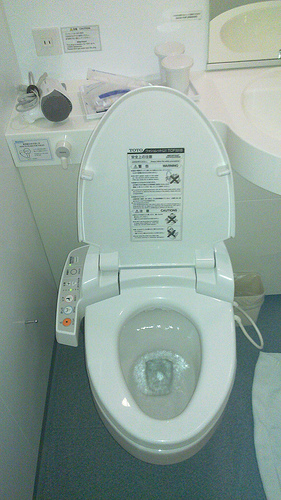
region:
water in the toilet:
[131, 353, 183, 387]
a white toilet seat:
[91, 284, 225, 439]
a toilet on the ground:
[81, 236, 239, 443]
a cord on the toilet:
[231, 304, 267, 347]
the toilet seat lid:
[82, 105, 219, 234]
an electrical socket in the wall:
[32, 27, 58, 51]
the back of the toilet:
[7, 67, 210, 123]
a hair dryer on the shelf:
[17, 72, 74, 115]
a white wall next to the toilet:
[8, 206, 32, 419]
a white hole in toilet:
[123, 311, 192, 459]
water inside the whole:
[130, 350, 180, 395]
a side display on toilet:
[46, 252, 87, 351]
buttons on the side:
[52, 251, 72, 339]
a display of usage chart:
[128, 138, 205, 253]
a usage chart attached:
[125, 149, 188, 248]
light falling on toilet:
[113, 388, 135, 411]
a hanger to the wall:
[19, 313, 41, 330]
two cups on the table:
[149, 25, 195, 88]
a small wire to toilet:
[234, 312, 279, 350]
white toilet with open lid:
[51, 86, 261, 472]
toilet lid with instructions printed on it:
[114, 133, 200, 254]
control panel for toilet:
[56, 239, 88, 351]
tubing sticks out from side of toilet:
[231, 294, 271, 358]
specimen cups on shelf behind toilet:
[153, 39, 195, 92]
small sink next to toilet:
[227, 77, 278, 167]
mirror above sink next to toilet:
[201, 4, 275, 77]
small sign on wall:
[59, 23, 109, 54]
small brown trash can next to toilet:
[233, 268, 268, 327]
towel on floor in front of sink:
[250, 343, 279, 498]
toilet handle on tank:
[52, 139, 72, 170]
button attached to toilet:
[52, 318, 75, 330]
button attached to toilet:
[59, 304, 76, 314]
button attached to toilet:
[60, 294, 73, 301]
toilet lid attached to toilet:
[76, 81, 255, 272]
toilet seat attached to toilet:
[84, 263, 234, 452]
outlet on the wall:
[31, 27, 63, 57]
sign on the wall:
[57, 25, 102, 54]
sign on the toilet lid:
[124, 144, 186, 244]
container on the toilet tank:
[155, 56, 199, 92]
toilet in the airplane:
[49, 248, 260, 475]